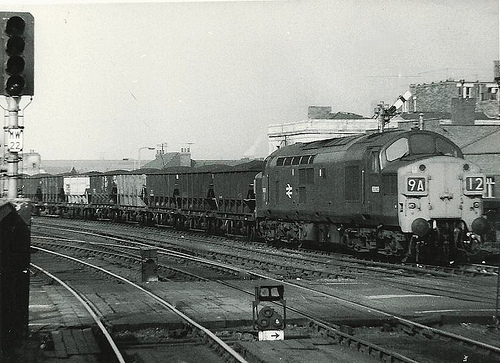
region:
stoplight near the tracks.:
[5, 22, 34, 94]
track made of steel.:
[108, 340, 129, 361]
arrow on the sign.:
[269, 330, 281, 339]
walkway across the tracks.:
[188, 288, 248, 303]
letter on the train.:
[414, 178, 424, 199]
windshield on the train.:
[411, 137, 431, 153]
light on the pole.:
[145, 144, 154, 154]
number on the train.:
[465, 175, 483, 191]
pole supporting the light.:
[0, 164, 20, 191]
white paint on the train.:
[279, 182, 293, 208]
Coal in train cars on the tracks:
[26, 155, 258, 234]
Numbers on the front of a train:
[407, 176, 426, 196]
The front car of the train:
[261, 124, 488, 257]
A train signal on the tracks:
[249, 281, 292, 346]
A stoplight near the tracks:
[1, 8, 41, 340]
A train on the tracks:
[21, 118, 499, 278]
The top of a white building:
[266, 119, 379, 135]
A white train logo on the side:
[281, 183, 296, 198]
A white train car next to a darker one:
[63, 173, 118, 206]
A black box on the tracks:
[143, 246, 162, 283]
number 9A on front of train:
[403, 171, 429, 203]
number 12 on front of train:
[464, 175, 485, 191]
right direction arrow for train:
[261, 327, 288, 342]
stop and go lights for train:
[4, 12, 33, 97]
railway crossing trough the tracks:
[328, 267, 428, 312]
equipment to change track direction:
[252, 284, 288, 328]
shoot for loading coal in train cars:
[372, 91, 414, 124]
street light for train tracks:
[134, 145, 157, 167]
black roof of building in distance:
[152, 144, 194, 168]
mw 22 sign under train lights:
[7, 127, 25, 152]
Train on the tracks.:
[22, 128, 497, 264]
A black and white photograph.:
[0, 5, 497, 361]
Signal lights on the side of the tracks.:
[2, 13, 36, 108]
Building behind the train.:
[267, 105, 408, 147]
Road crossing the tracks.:
[29, 274, 498, 326]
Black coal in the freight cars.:
[86, 163, 267, 175]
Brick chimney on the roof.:
[450, 94, 479, 124]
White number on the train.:
[462, 175, 485, 195]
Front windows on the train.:
[377, 126, 465, 161]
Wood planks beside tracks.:
[52, 324, 102, 361]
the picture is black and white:
[4, 125, 481, 360]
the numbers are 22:
[3, 131, 38, 149]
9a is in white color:
[399, 166, 427, 193]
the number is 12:
[461, 169, 489, 196]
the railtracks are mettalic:
[78, 213, 243, 340]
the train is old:
[74, 128, 472, 283]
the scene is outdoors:
[1, 128, 491, 356]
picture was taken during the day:
[1, 124, 493, 361]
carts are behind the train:
[22, 167, 259, 228]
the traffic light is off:
[0, 18, 30, 100]